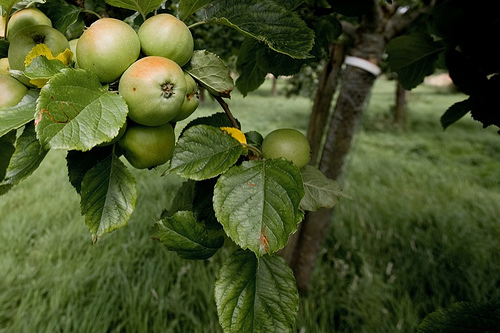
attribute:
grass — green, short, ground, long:
[2, 78, 499, 332]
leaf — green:
[212, 158, 306, 271]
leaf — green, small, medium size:
[160, 123, 243, 180]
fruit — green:
[118, 55, 188, 126]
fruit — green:
[76, 18, 140, 85]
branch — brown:
[215, 96, 240, 130]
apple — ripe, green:
[139, 13, 194, 68]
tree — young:
[0, 1, 317, 333]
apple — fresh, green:
[260, 129, 311, 173]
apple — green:
[6, 24, 70, 89]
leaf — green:
[36, 68, 129, 154]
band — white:
[342, 53, 382, 77]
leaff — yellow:
[214, 124, 245, 146]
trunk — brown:
[274, 1, 397, 297]